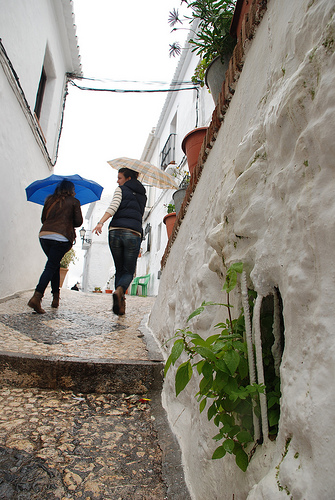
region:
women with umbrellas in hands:
[11, 147, 147, 317]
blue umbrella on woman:
[21, 167, 101, 211]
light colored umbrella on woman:
[104, 149, 178, 191]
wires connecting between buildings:
[70, 71, 208, 108]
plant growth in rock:
[162, 252, 278, 456]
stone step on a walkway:
[2, 333, 152, 410]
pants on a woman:
[106, 228, 136, 288]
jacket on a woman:
[42, 194, 81, 235]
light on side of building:
[78, 224, 90, 238]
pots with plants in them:
[156, 122, 212, 250]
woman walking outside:
[23, 117, 222, 348]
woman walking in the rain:
[29, 143, 206, 346]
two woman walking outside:
[42, 148, 259, 374]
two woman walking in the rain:
[17, 140, 203, 385]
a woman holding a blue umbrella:
[4, 144, 104, 283]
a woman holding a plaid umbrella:
[94, 147, 220, 325]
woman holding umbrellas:
[24, 149, 220, 320]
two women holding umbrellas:
[19, 139, 242, 418]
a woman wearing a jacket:
[18, 147, 202, 327]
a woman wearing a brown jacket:
[15, 179, 106, 296]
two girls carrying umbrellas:
[15, 143, 176, 323]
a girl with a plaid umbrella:
[101, 153, 176, 323]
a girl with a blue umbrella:
[18, 165, 106, 307]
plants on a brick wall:
[147, 5, 236, 236]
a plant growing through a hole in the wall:
[162, 235, 304, 479]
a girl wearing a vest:
[108, 163, 152, 232]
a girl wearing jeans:
[104, 221, 146, 297]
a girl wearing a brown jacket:
[37, 189, 87, 242]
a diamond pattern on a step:
[2, 289, 130, 352]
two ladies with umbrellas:
[12, 137, 185, 337]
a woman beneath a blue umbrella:
[24, 172, 104, 311]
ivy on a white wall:
[161, 261, 278, 469]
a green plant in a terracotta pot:
[162, 201, 180, 238]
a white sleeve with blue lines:
[107, 187, 122, 219]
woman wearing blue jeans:
[108, 229, 142, 288]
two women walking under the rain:
[26, 158, 179, 313]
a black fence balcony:
[161, 135, 175, 166]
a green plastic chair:
[131, 274, 152, 294]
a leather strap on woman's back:
[44, 194, 66, 226]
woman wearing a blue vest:
[110, 179, 147, 238]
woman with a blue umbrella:
[25, 173, 104, 312]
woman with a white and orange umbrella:
[91, 156, 177, 314]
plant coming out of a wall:
[165, 262, 278, 471]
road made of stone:
[0, 284, 167, 498]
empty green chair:
[130, 274, 151, 297]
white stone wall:
[148, 0, 334, 499]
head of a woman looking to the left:
[117, 167, 137, 186]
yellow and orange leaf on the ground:
[138, 398, 152, 401]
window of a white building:
[36, 45, 57, 137]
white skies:
[52, 0, 195, 290]